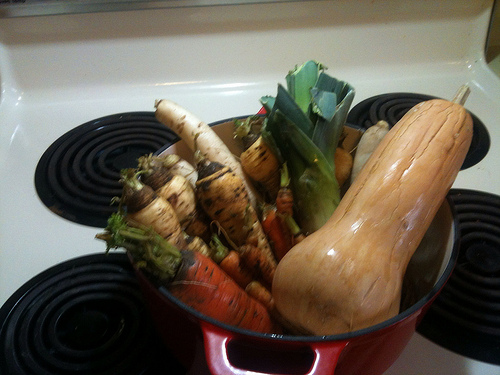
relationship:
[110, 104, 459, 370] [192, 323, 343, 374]
bowl has handle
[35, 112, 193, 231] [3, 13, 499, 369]
burner on stove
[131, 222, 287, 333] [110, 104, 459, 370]
carrot in bowl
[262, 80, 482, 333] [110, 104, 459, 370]
squash in bowl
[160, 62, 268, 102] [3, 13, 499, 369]
reflection on stove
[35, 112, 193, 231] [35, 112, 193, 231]
burner on burner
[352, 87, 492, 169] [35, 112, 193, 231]
burner on burner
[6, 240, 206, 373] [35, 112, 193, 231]
burner on burner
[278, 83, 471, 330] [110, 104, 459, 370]
vegetable in bowl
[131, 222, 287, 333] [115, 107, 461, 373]
carrot in pot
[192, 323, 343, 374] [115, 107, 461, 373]
handle on pot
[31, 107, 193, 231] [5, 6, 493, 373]
burner on oven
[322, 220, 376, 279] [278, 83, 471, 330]
shine on vegetable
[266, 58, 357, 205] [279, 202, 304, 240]
stem on veggies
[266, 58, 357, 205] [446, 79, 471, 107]
stem on veggies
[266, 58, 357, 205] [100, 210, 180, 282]
stem on veggies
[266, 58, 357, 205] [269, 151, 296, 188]
stem on veggies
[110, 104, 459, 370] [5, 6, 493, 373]
bowl on oven